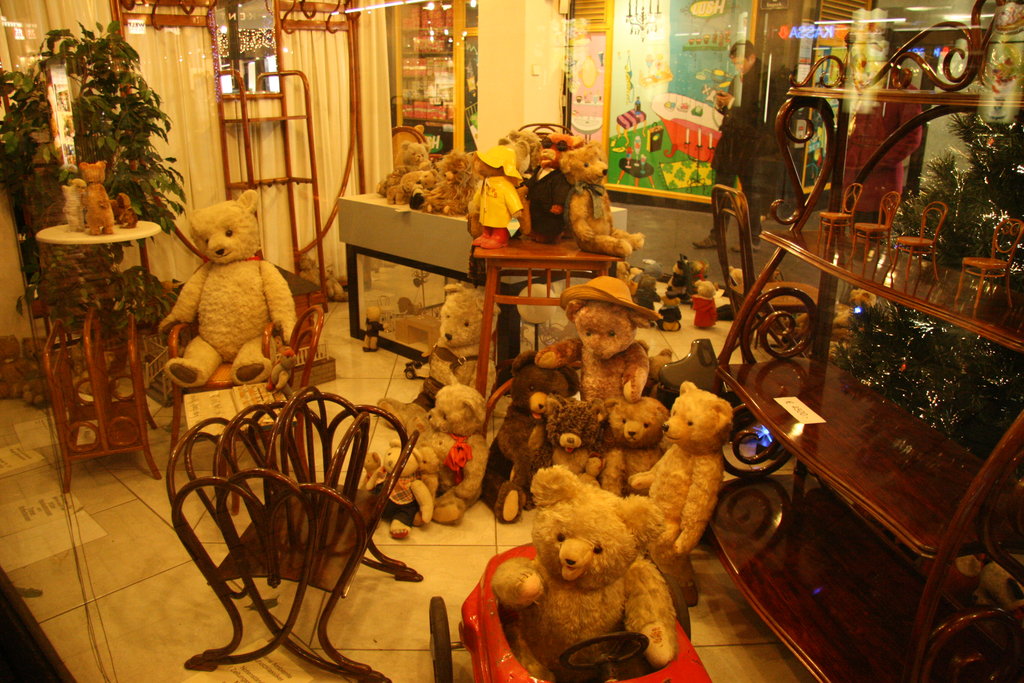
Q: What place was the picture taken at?
A: It was taken at the store.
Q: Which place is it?
A: It is a store.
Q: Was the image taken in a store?
A: Yes, it was taken in a store.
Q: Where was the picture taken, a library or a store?
A: It was taken at a store.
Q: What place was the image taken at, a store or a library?
A: It was taken at a store.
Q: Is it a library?
A: No, it is a store.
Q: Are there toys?
A: Yes, there is a toy.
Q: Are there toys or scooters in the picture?
A: Yes, there is a toy.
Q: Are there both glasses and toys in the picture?
A: No, there is a toy but no glasses.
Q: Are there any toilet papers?
A: No, there are no toilet papers.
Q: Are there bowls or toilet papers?
A: No, there are no toilet papers or bowls.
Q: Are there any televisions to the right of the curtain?
A: No, there is a toy to the right of the curtain.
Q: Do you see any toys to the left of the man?
A: Yes, there is a toy to the left of the man.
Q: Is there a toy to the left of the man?
A: Yes, there is a toy to the left of the man.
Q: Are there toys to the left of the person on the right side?
A: Yes, there is a toy to the left of the man.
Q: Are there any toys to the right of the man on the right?
A: No, the toy is to the left of the man.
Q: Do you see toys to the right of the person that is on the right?
A: No, the toy is to the left of the man.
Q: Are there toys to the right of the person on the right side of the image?
A: No, the toy is to the left of the man.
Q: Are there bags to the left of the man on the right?
A: No, there is a toy to the left of the man.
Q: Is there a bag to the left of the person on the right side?
A: No, there is a toy to the left of the man.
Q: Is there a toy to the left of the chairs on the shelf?
A: Yes, there is a toy to the left of the chairs.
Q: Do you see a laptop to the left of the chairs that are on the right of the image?
A: No, there is a toy to the left of the chairs.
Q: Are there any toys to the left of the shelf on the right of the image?
A: Yes, there is a toy to the left of the shelf.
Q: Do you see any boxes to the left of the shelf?
A: No, there is a toy to the left of the shelf.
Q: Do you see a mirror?
A: No, there are no mirrors.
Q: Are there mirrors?
A: No, there are no mirrors.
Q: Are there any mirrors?
A: No, there are no mirrors.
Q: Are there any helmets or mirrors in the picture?
A: No, there are no mirrors or helmets.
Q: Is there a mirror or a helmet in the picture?
A: No, there are no mirrors or helmets.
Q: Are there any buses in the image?
A: No, there are no buses.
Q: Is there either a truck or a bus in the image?
A: No, there are no buses or trucks.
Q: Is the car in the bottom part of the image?
A: Yes, the car is in the bottom of the image.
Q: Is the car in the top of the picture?
A: No, the car is in the bottom of the image.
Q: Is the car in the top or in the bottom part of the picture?
A: The car is in the bottom of the image.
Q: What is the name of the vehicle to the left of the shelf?
A: The vehicle is a car.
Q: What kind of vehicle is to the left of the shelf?
A: The vehicle is a car.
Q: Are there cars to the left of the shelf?
A: Yes, there is a car to the left of the shelf.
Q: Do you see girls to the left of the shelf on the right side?
A: No, there is a car to the left of the shelf.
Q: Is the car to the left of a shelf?
A: Yes, the car is to the left of a shelf.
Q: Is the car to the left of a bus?
A: No, the car is to the left of a shelf.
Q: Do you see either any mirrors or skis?
A: No, there are no mirrors or skis.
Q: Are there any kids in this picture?
A: No, there are no kids.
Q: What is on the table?
A: The teddy bears are on the table.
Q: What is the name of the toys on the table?
A: The toys are teddy bears.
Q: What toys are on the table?
A: The toys are teddy bears.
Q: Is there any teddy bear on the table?
A: Yes, there are teddy bears on the table.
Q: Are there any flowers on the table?
A: No, there are teddy bears on the table.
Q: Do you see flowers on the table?
A: No, there are teddy bears on the table.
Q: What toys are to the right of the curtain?
A: The toys are teddy bears.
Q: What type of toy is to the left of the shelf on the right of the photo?
A: The toys are teddy bears.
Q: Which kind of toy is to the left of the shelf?
A: The toys are teddy bears.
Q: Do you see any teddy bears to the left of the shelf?
A: Yes, there are teddy bears to the left of the shelf.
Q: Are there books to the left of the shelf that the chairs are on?
A: No, there are teddy bears to the left of the shelf.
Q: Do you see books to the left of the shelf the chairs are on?
A: No, there are teddy bears to the left of the shelf.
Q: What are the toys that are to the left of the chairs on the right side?
A: The toys are teddy bears.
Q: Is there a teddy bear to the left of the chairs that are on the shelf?
A: Yes, there are teddy bears to the left of the chairs.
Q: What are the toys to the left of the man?
A: The toys are teddy bears.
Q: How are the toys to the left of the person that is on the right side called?
A: The toys are teddy bears.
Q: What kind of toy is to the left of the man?
A: The toys are teddy bears.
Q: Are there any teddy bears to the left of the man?
A: Yes, there are teddy bears to the left of the man.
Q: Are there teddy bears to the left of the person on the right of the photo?
A: Yes, there are teddy bears to the left of the man.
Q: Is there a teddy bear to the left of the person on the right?
A: Yes, there are teddy bears to the left of the man.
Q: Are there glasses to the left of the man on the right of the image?
A: No, there are teddy bears to the left of the man.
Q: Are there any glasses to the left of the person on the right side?
A: No, there are teddy bears to the left of the man.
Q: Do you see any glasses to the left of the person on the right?
A: No, there are teddy bears to the left of the man.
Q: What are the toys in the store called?
A: The toys are teddy bears.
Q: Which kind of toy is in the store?
A: The toys are teddy bears.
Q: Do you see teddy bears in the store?
A: Yes, there are teddy bears in the store.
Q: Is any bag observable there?
A: No, there are no bags.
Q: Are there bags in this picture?
A: No, there are no bags.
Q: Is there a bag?
A: No, there are no bags.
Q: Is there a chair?
A: Yes, there is a chair.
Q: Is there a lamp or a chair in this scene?
A: Yes, there is a chair.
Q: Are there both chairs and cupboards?
A: No, there is a chair but no cupboards.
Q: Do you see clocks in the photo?
A: No, there are no clocks.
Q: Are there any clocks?
A: No, there are no clocks.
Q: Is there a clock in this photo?
A: No, there are no clocks.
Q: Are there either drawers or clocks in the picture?
A: No, there are no clocks or drawers.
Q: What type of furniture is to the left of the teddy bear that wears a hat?
A: The piece of furniture is a chair.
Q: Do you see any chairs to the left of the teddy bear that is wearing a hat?
A: Yes, there is a chair to the left of the teddy bear.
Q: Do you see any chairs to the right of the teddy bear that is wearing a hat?
A: No, the chair is to the left of the teddy bear.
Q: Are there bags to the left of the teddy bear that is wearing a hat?
A: No, there is a chair to the left of the teddy bear.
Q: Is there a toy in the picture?
A: Yes, there is a toy.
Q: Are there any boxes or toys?
A: Yes, there is a toy.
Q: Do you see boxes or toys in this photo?
A: Yes, there is a toy.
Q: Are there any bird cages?
A: No, there are no bird cages.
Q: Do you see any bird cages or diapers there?
A: No, there are no bird cages or diapers.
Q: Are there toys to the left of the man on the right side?
A: Yes, there is a toy to the left of the man.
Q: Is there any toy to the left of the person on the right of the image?
A: Yes, there is a toy to the left of the man.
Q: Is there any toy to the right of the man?
A: No, the toy is to the left of the man.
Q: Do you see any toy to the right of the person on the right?
A: No, the toy is to the left of the man.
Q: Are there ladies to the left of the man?
A: No, there is a toy to the left of the man.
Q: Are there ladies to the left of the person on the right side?
A: No, there is a toy to the left of the man.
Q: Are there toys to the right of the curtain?
A: Yes, there is a toy to the right of the curtain.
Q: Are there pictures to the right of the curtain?
A: No, there is a toy to the right of the curtain.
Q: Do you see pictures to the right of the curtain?
A: No, there is a toy to the right of the curtain.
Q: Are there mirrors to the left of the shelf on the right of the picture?
A: No, there is a toy to the left of the shelf.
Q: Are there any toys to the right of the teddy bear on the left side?
A: Yes, there is a toy to the right of the teddy bear.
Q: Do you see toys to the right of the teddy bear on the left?
A: Yes, there is a toy to the right of the teddy bear.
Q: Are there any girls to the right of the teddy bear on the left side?
A: No, there is a toy to the right of the teddy bear.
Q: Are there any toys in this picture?
A: Yes, there is a toy.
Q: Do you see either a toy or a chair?
A: Yes, there is a toy.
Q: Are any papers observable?
A: No, there are no papers.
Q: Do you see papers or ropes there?
A: No, there are no papers or ropes.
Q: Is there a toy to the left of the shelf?
A: Yes, there is a toy to the left of the shelf.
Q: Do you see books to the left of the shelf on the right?
A: No, there is a toy to the left of the shelf.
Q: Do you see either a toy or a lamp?
A: Yes, there is a toy.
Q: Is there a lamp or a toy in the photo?
A: Yes, there is a toy.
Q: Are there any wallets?
A: No, there are no wallets.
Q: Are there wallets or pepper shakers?
A: No, there are no wallets or pepper shakers.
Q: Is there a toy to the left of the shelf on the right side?
A: Yes, there is a toy to the left of the shelf.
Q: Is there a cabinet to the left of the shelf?
A: No, there is a toy to the left of the shelf.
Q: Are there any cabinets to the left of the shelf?
A: No, there is a toy to the left of the shelf.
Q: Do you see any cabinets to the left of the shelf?
A: No, there is a toy to the left of the shelf.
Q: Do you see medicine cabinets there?
A: No, there are no medicine cabinets.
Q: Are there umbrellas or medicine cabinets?
A: No, there are no medicine cabinets or umbrellas.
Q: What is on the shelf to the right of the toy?
A: The chairs are on the shelf.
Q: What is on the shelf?
A: The chairs are on the shelf.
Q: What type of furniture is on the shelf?
A: The pieces of furniture are chairs.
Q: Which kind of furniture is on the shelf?
A: The pieces of furniture are chairs.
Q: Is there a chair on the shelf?
A: Yes, there are chairs on the shelf.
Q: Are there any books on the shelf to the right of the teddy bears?
A: No, there are chairs on the shelf.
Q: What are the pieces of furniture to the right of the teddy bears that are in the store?
A: The pieces of furniture are chairs.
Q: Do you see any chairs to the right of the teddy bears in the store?
A: Yes, there are chairs to the right of the teddy bears.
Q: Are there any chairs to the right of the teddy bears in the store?
A: Yes, there are chairs to the right of the teddy bears.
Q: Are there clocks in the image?
A: No, there are no clocks.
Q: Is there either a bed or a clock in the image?
A: No, there are no clocks or beds.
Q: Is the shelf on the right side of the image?
A: Yes, the shelf is on the right of the image.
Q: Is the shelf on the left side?
A: No, the shelf is on the right of the image.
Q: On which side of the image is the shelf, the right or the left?
A: The shelf is on the right of the image.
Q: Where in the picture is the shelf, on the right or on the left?
A: The shelf is on the right of the image.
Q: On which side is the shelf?
A: The shelf is on the right of the image.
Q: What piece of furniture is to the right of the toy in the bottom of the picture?
A: The piece of furniture is a shelf.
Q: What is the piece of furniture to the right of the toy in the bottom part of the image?
A: The piece of furniture is a shelf.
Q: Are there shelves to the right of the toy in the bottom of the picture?
A: Yes, there is a shelf to the right of the toy.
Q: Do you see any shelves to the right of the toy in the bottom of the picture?
A: Yes, there is a shelf to the right of the toy.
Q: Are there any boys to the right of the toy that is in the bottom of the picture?
A: No, there is a shelf to the right of the toy.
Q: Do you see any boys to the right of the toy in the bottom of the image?
A: No, there is a shelf to the right of the toy.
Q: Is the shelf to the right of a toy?
A: Yes, the shelf is to the right of a toy.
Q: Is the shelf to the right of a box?
A: No, the shelf is to the right of a toy.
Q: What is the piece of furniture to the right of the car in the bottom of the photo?
A: The piece of furniture is a shelf.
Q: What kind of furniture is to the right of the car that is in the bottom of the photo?
A: The piece of furniture is a shelf.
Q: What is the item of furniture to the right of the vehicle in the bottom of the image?
A: The piece of furniture is a shelf.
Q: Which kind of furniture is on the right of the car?
A: The piece of furniture is a shelf.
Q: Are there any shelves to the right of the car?
A: Yes, there is a shelf to the right of the car.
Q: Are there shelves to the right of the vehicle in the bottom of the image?
A: Yes, there is a shelf to the right of the car.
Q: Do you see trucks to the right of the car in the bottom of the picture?
A: No, there is a shelf to the right of the car.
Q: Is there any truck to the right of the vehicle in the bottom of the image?
A: No, there is a shelf to the right of the car.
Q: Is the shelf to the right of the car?
A: Yes, the shelf is to the right of the car.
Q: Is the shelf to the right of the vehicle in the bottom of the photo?
A: Yes, the shelf is to the right of the car.